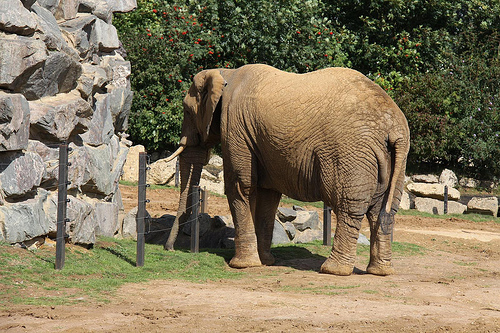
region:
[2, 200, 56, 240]
The rock is gray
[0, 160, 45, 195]
The rock is gray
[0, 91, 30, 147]
The rock is gray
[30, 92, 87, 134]
The rock is gray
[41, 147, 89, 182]
The rock is gray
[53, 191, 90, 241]
The rock is gray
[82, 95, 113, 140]
The rock is gray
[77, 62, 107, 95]
The rock is gray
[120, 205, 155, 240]
The rock is gray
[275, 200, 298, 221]
The rock is gray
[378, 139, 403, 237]
the tail of the elephant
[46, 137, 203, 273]
the fence on front of the elephant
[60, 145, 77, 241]
the hooks on the post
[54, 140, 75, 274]
the black post on the fence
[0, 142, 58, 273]
the wire fence in front of the rocks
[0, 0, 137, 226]
the rock wall in front of the elephant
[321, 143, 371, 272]
the wrinkles on the leg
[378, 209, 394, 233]
the hair on the end of the tail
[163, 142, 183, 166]
the tusk on the face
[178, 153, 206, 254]
the trunk eating the grass on the ground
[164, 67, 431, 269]
elephant is light brown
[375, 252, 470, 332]
ground is light brown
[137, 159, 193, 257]
elephant has long trunk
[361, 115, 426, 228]
elephant has short tail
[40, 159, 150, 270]
dark grey fence posts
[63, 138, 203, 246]
thin wires on fence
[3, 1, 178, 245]
grey rocks behind fence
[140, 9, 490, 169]
green trees behind wall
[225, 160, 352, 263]
light brown legs on elephant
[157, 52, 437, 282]
one elephant in grass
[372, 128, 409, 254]
elephant tail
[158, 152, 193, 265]
elephant trunk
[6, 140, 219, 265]
wood and metal fence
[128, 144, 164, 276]
fence support pole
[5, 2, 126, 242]
rock wall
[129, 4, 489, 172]
tall green trees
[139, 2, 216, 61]
red berries in tree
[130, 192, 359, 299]
black shadow under elephant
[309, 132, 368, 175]
wrinkles on elephant skin